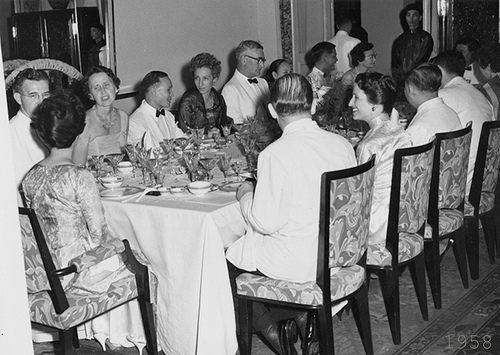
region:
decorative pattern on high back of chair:
[319, 163, 379, 270]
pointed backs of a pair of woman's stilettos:
[91, 325, 148, 354]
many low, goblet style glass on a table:
[126, 137, 243, 188]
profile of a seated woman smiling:
[344, 69, 407, 151]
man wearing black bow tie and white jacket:
[221, 35, 277, 125]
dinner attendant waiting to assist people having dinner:
[388, 0, 437, 87]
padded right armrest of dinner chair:
[66, 235, 128, 275]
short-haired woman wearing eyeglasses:
[339, 38, 380, 86]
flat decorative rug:
[443, 288, 498, 353]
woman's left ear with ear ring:
[363, 94, 388, 117]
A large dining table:
[88, 109, 414, 224]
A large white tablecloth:
[26, 113, 414, 353]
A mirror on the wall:
[0, 0, 120, 77]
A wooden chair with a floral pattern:
[236, 155, 376, 354]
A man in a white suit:
[224, 75, 354, 353]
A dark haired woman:
[347, 69, 412, 246]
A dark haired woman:
[21, 93, 154, 353]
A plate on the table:
[98, 185, 142, 199]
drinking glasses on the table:
[92, 125, 267, 185]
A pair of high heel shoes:
[89, 330, 160, 354]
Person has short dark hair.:
[81, 63, 141, 109]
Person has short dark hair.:
[140, 61, 172, 96]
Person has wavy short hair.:
[181, 44, 239, 76]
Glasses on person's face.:
[246, 53, 280, 78]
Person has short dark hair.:
[309, 39, 354, 88]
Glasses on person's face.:
[361, 50, 385, 63]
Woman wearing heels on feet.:
[90, 325, 139, 352]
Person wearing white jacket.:
[263, 162, 343, 261]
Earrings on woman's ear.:
[367, 100, 376, 114]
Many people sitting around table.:
[25, 52, 457, 282]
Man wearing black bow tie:
[219, 38, 271, 128]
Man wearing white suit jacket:
[219, 35, 269, 120]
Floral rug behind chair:
[352, 245, 498, 353]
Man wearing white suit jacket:
[228, 73, 358, 354]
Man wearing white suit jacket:
[402, 60, 464, 147]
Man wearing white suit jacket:
[432, 47, 494, 194]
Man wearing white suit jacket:
[130, 69, 187, 148]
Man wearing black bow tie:
[128, 69, 186, 143]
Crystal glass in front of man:
[214, 152, 236, 180]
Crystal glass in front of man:
[91, 151, 107, 180]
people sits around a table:
[5, 3, 490, 353]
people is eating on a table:
[14, 16, 499, 348]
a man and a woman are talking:
[129, 55, 237, 147]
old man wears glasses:
[225, 28, 276, 106]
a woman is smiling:
[336, 63, 407, 147]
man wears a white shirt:
[122, 60, 189, 142]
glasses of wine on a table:
[99, 134, 247, 183]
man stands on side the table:
[388, 6, 440, 70]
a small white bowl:
[183, 177, 213, 199]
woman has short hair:
[176, 52, 236, 130]